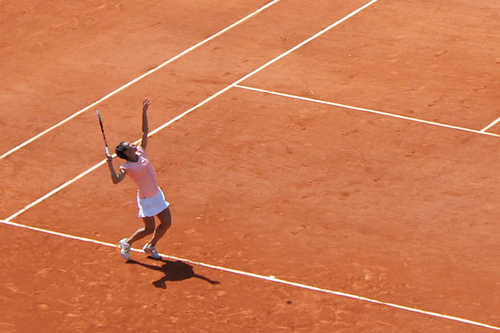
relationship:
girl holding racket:
[104, 98, 170, 260] [95, 110, 110, 156]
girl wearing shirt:
[104, 98, 170, 260] [118, 144, 158, 198]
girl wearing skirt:
[104, 98, 170, 260] [134, 187, 171, 218]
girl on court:
[104, 98, 170, 260] [2, 0, 499, 330]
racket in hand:
[97, 110, 111, 156] [103, 152, 113, 164]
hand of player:
[103, 152, 113, 164] [103, 97, 173, 260]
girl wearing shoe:
[104, 98, 170, 260] [139, 245, 163, 262]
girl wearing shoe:
[104, 98, 170, 260] [119, 239, 130, 263]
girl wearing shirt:
[104, 98, 170, 260] [112, 155, 162, 194]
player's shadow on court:
[123, 245, 223, 291] [2, 0, 499, 330]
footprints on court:
[29, 281, 170, 324] [2, 0, 499, 330]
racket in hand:
[97, 110, 111, 156] [106, 153, 113, 165]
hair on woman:
[108, 140, 140, 168] [88, 87, 188, 267]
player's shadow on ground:
[125, 255, 220, 289] [1, 0, 498, 330]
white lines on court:
[28, 17, 470, 308] [2, 0, 499, 330]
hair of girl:
[115, 141, 127, 158] [104, 98, 170, 260]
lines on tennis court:
[2, 2, 497, 331] [4, 2, 498, 331]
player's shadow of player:
[125, 255, 220, 289] [86, 96, 183, 263]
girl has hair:
[104, 98, 170, 260] [114, 133, 125, 160]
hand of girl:
[106, 154, 113, 163] [104, 98, 170, 260]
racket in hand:
[97, 110, 111, 156] [106, 154, 113, 163]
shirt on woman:
[119, 146, 160, 199] [108, 127, 177, 250]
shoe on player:
[115, 240, 136, 265] [94, 98, 172, 261]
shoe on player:
[120, 238, 134, 260] [73, 64, 223, 263]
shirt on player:
[119, 146, 160, 199] [116, 129, 220, 239]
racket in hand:
[97, 110, 111, 156] [98, 146, 117, 167]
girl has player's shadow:
[104, 98, 170, 260] [125, 255, 220, 289]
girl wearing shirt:
[104, 98, 170, 260] [117, 142, 169, 201]